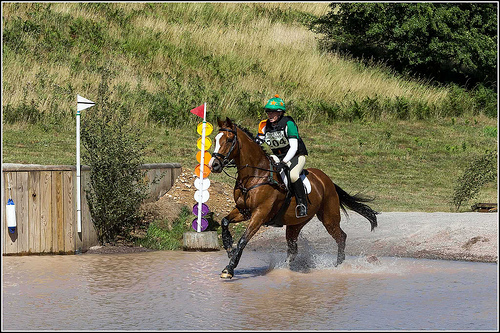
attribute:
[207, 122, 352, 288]
horse — brown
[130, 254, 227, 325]
water — brown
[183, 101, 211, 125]
flag — red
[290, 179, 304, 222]
boots — black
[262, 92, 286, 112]
helmet — green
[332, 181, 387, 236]
tail — black, blck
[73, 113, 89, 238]
pole — white